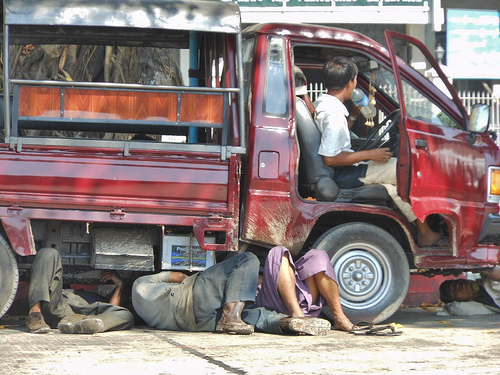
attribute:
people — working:
[26, 247, 369, 337]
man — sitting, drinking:
[313, 55, 452, 247]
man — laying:
[259, 244, 364, 333]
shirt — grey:
[132, 271, 208, 331]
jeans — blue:
[193, 251, 290, 335]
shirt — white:
[312, 92, 358, 166]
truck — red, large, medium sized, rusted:
[0, 0, 499, 327]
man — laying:
[439, 268, 499, 316]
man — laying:
[24, 247, 135, 333]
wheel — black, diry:
[309, 222, 410, 330]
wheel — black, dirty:
[0, 235, 20, 320]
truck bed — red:
[0, 2, 242, 256]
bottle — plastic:
[351, 89, 377, 119]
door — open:
[384, 29, 487, 257]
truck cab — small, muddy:
[239, 23, 499, 270]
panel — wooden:
[12, 81, 230, 145]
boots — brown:
[216, 301, 332, 334]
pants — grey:
[27, 248, 131, 330]